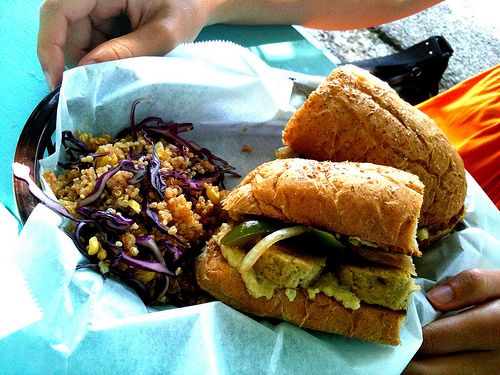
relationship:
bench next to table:
[43, 17, 495, 373] [48, 7, 463, 345]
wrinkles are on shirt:
[437, 78, 495, 188] [416, 57, 499, 208]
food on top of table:
[59, 68, 470, 348] [0, 0, 499, 221]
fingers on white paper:
[401, 279, 499, 374] [2, 36, 499, 371]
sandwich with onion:
[195, 157, 426, 346] [242, 219, 312, 293]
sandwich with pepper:
[195, 157, 426, 346] [302, 220, 342, 290]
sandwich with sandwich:
[195, 157, 426, 346] [195, 157, 426, 346]